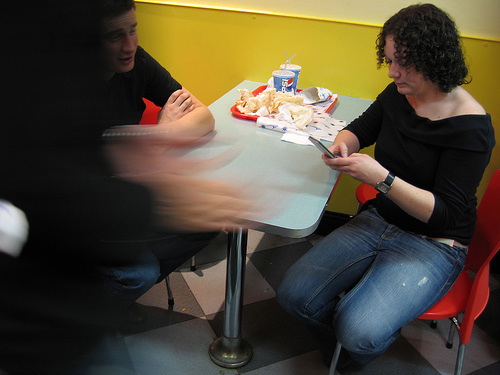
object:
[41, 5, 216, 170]
man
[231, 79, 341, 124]
tray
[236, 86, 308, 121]
food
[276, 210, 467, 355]
jeans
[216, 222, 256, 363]
pole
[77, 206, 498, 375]
floor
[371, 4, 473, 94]
curly hair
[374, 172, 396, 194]
watch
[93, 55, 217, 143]
arms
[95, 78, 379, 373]
table